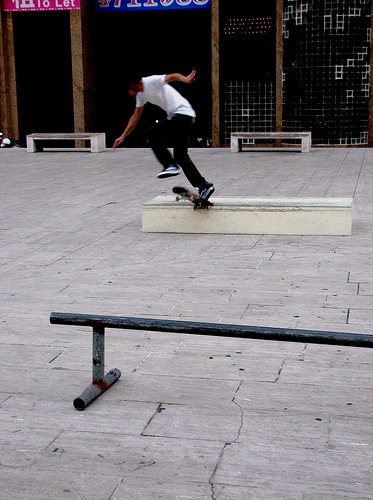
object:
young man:
[112, 65, 215, 201]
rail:
[49, 313, 373, 412]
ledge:
[141, 195, 353, 237]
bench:
[229, 130, 310, 153]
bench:
[25, 133, 106, 154]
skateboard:
[171, 186, 214, 211]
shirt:
[136, 73, 195, 120]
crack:
[231, 309, 350, 498]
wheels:
[189, 195, 196, 201]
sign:
[1, 0, 82, 13]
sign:
[96, 1, 213, 10]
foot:
[156, 164, 181, 179]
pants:
[145, 112, 212, 188]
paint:
[90, 378, 107, 389]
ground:
[1, 146, 372, 499]